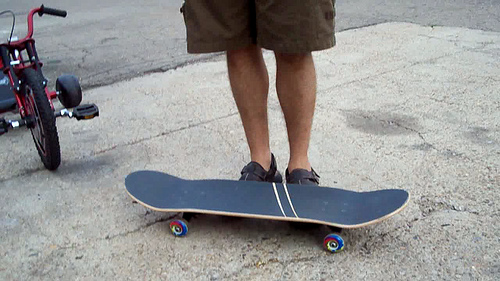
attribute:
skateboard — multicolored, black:
[113, 133, 440, 265]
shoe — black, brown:
[216, 134, 327, 206]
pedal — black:
[53, 87, 116, 147]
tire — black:
[3, 59, 68, 179]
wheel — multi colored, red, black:
[165, 220, 197, 236]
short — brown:
[168, 8, 347, 68]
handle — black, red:
[39, 4, 70, 22]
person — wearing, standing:
[180, 10, 368, 195]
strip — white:
[267, 172, 308, 222]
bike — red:
[19, 24, 100, 163]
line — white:
[243, 159, 319, 219]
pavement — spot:
[332, 69, 474, 162]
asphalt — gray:
[107, 18, 154, 65]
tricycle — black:
[1, 33, 92, 190]